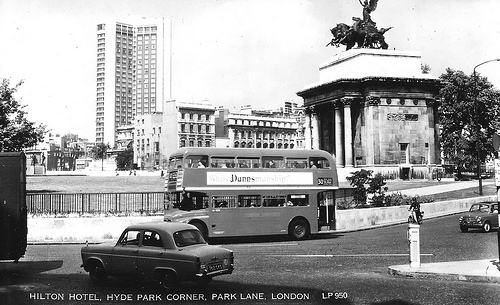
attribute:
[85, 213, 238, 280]
car — going left, turning, small, on right, old-fashioned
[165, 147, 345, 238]
bus — doubledecker, filled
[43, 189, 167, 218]
railings — behind street, on road, iron, grated, tiny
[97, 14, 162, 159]
building — large, tall, white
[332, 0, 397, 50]
statue — of horse, dark, riding chariot, of angel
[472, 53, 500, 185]
post — black, on far right, streetlight, tall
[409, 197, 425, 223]
person — riding bicycle, riding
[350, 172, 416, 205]
trees — lining street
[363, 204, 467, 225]
curb — white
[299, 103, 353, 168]
pillars — four, on building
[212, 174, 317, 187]
sign — on bus, white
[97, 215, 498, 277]
road — busy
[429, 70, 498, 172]
tree — on right, leafy, large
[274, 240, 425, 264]
line — white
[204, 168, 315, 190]
rectangle — white